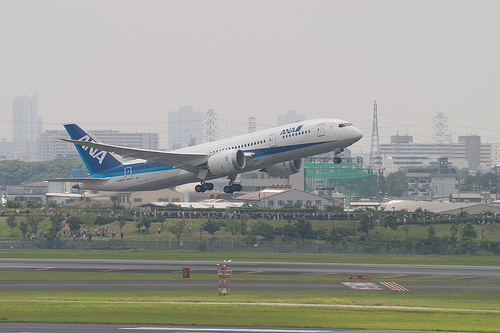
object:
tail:
[56, 120, 127, 179]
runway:
[58, 259, 309, 293]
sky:
[142, 15, 292, 73]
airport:
[3, 85, 483, 328]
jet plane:
[42, 115, 363, 195]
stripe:
[99, 162, 159, 175]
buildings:
[370, 110, 498, 212]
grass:
[361, 305, 459, 329]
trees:
[4, 210, 65, 242]